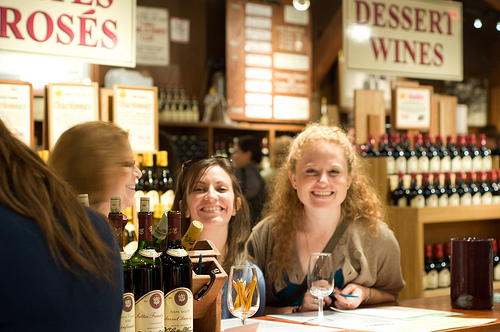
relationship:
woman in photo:
[281, 132, 377, 301] [18, 23, 483, 314]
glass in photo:
[301, 255, 337, 324] [18, 23, 483, 314]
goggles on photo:
[179, 152, 237, 166] [18, 23, 483, 314]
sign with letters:
[343, 10, 469, 82] [378, 9, 437, 69]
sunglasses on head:
[176, 154, 233, 171] [183, 163, 236, 224]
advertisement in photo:
[336, 10, 483, 80] [18, 23, 483, 314]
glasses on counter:
[224, 248, 346, 320] [255, 303, 483, 332]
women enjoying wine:
[60, 125, 384, 293] [140, 203, 197, 327]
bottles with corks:
[82, 193, 163, 319] [75, 193, 153, 210]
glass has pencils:
[223, 254, 259, 328] [240, 275, 256, 313]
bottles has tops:
[387, 138, 487, 197] [417, 134, 444, 142]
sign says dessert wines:
[343, 10, 469, 82] [358, 5, 456, 60]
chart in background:
[227, 3, 302, 115] [126, 1, 453, 97]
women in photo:
[60, 125, 384, 293] [18, 23, 483, 314]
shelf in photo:
[161, 107, 325, 133] [18, 23, 483, 314]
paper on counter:
[355, 308, 425, 328] [255, 303, 483, 332]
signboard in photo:
[238, 16, 320, 122] [18, 23, 483, 314]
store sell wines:
[55, 38, 493, 249] [363, 127, 499, 254]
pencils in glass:
[240, 275, 256, 313] [223, 254, 259, 328]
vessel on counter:
[448, 232, 497, 297] [255, 303, 483, 332]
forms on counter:
[332, 311, 468, 328] [255, 303, 483, 332]